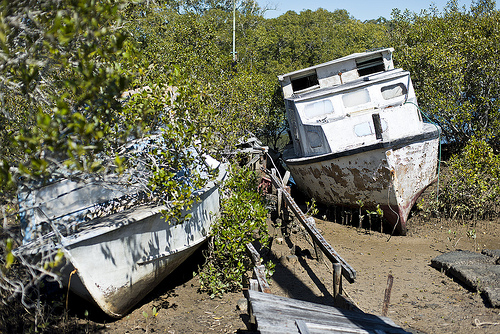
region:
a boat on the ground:
[264, 23, 474, 228]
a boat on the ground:
[251, 45, 496, 233]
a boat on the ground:
[248, 33, 495, 251]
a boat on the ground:
[280, 29, 452, 219]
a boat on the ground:
[258, 21, 492, 248]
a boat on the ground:
[260, 33, 494, 238]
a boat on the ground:
[227, 53, 452, 204]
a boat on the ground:
[304, 61, 494, 259]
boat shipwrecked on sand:
[258, 38, 463, 233]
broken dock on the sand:
[232, 281, 404, 331]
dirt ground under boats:
[348, 232, 433, 314]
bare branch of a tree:
[2, 259, 69, 320]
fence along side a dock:
[262, 145, 369, 294]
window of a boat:
[290, 71, 319, 91]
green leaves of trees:
[126, 22, 231, 90]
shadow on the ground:
[254, 246, 309, 297]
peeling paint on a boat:
[333, 161, 390, 202]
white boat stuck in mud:
[261, 43, 438, 253]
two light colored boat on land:
[23, 42, 445, 329]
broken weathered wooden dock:
[231, 277, 404, 332]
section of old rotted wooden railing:
[261, 162, 362, 297]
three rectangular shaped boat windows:
[294, 74, 414, 123]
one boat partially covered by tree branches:
[7, 89, 230, 318]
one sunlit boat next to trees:
[272, 42, 441, 234]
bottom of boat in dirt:
[358, 192, 432, 254]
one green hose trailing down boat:
[403, 94, 451, 188]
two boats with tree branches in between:
[25, 43, 445, 322]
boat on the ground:
[261, 20, 462, 229]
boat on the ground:
[6, 125, 268, 320]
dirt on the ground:
[369, 231, 486, 329]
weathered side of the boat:
[329, 165, 388, 195]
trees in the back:
[26, 7, 483, 177]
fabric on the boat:
[13, 199, 51, 249]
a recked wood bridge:
[232, 133, 392, 331]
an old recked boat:
[278, 48, 440, 228]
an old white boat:
[27, 134, 223, 315]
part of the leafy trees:
[6, 4, 92, 66]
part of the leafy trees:
[106, 12, 193, 77]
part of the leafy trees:
[216, 75, 268, 131]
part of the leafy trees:
[252, 29, 292, 66]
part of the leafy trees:
[325, 12, 367, 42]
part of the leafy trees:
[395, 23, 440, 54]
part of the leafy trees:
[441, 66, 483, 119]